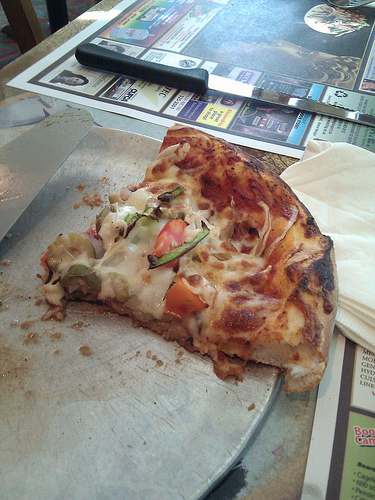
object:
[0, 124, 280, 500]
plate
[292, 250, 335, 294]
spot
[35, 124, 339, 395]
pizza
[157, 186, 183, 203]
peppers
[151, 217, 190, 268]
tomatoes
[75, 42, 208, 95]
handle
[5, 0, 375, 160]
newspaper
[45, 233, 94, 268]
onions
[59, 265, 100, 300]
olives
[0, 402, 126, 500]
server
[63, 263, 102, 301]
mushroom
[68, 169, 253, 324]
cheese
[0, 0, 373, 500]
table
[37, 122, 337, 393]
slice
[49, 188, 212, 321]
toppings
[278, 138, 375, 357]
white napkins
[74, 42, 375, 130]
knife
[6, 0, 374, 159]
placemat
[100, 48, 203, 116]
ads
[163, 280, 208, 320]
tomato slice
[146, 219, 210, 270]
green pepper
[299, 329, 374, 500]
placemat